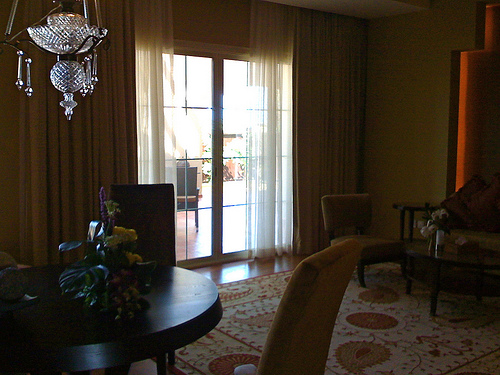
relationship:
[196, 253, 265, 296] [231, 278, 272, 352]
floor has carpet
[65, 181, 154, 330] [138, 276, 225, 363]
flowers on table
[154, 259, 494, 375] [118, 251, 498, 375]
rug on floor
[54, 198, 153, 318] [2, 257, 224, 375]
arrangement on table